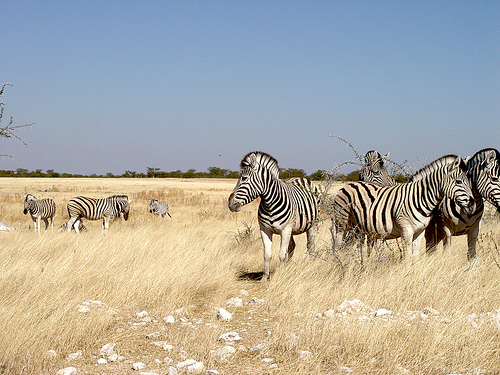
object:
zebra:
[226, 151, 318, 284]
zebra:
[330, 155, 474, 273]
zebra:
[362, 150, 394, 184]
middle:
[355, 149, 397, 189]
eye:
[240, 174, 248, 181]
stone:
[216, 303, 234, 321]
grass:
[0, 188, 498, 373]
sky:
[0, 0, 499, 178]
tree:
[147, 166, 160, 177]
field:
[0, 175, 499, 374]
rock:
[216, 307, 233, 321]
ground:
[0, 175, 499, 374]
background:
[0, 0, 499, 375]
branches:
[0, 82, 35, 160]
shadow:
[240, 271, 266, 281]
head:
[228, 151, 281, 213]